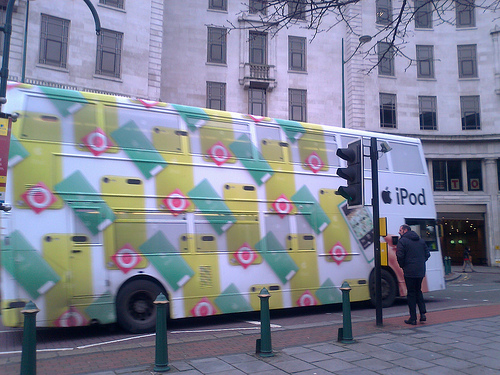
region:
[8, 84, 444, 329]
double decker bus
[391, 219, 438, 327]
man standing beside the bus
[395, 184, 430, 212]
black lettering on white background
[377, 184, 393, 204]
apple logo on the bus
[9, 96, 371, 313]
advertisement on the side of the bus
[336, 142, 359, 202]
black traffic signal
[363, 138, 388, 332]
black pole traffic signal is attached to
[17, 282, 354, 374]
green pillars on the sidewalk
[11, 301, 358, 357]
white lines painted on the street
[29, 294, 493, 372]
sidewalk the man is standing on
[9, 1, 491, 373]
a scene outside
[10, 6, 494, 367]
a photo of downtown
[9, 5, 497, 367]
a scene during the day time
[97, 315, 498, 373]
a gray tile sidewalk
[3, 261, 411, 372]
a green row of posts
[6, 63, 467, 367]
a huge white double decker bus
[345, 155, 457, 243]
words iPAD on the bus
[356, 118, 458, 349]
a person next to the crosswalk crossing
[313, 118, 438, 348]
a traffic light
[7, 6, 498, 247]
a white building in the background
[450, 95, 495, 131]
window on a building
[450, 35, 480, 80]
window on a building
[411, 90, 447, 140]
window on a building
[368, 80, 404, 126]
window on a building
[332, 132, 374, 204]
traffic sign on a pole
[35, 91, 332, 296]
bus on a street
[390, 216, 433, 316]
man standing on a side walk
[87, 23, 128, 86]
window on a building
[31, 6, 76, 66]
window on a building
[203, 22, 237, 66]
window on a building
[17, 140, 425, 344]
white yellow and green bus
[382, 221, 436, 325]
man is outside bus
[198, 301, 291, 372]
white lines on road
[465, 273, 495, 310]
road is dark grey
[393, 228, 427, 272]
man has black coat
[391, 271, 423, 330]
man has black pants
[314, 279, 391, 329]
green posts near bus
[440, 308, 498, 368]
dark grey concrete near man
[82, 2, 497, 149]
light grey exterior on building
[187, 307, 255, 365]
red brick on sidewalk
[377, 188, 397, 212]
The logo for apple company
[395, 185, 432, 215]
The IPod logo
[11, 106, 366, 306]
The small pink ipods on the bus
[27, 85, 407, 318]
The aqua ipods on the bus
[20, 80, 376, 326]
The green ipods on the bus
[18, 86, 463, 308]
A bus that is covered in ipods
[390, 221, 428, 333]
A person standing next to the bus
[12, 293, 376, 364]
The traffc poles next tot he bus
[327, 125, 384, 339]
The traffic signal next to the bus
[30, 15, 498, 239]
The buildings that are behind the bus